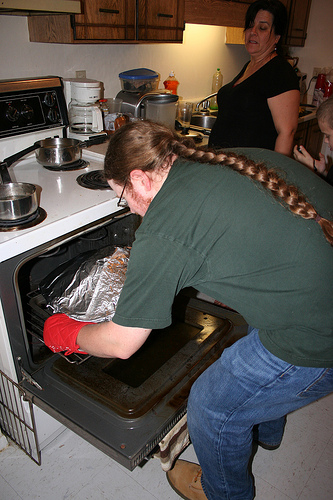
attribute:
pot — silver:
[39, 135, 83, 163]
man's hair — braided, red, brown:
[114, 125, 332, 239]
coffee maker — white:
[61, 76, 104, 138]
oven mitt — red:
[40, 312, 105, 356]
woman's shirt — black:
[212, 68, 296, 150]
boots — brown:
[167, 457, 212, 499]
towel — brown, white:
[154, 420, 197, 467]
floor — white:
[4, 434, 332, 498]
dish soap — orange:
[167, 73, 179, 97]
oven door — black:
[45, 300, 237, 451]